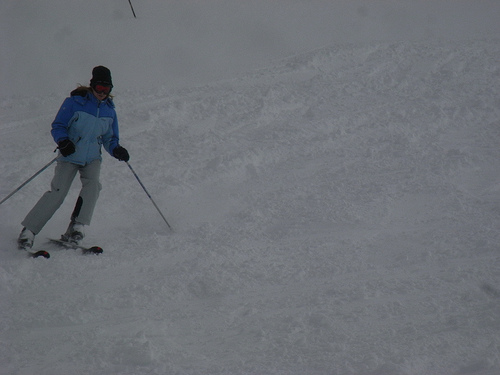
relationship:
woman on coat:
[18, 64, 130, 251] [50, 90, 118, 162]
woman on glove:
[18, 64, 130, 251] [109, 145, 130, 162]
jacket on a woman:
[40, 85, 124, 166] [18, 64, 130, 251]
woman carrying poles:
[18, 64, 130, 251] [126, 163, 176, 231]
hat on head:
[83, 60, 116, 94] [83, 51, 133, 102]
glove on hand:
[113, 143, 130, 160] [54, 134, 130, 165]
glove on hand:
[53, 137, 77, 157] [54, 134, 130, 165]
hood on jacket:
[70, 81, 95, 98] [50, 84, 123, 168]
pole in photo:
[1, 140, 71, 216] [2, 2, 483, 372]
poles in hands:
[0, 148, 176, 231] [59, 135, 134, 177]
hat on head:
[90, 65, 115, 86] [82, 51, 137, 103]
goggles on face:
[78, 76, 115, 102] [91, 76, 115, 95]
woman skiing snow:
[18, 64, 130, 251] [1, 0, 498, 374]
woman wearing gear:
[18, 64, 130, 251] [3, 141, 168, 247]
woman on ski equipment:
[18, 64, 130, 251] [23, 244, 51, 261]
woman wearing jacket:
[18, 64, 130, 251] [49, 87, 121, 163]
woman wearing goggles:
[18, 64, 130, 251] [92, 85, 113, 93]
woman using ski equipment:
[18, 64, 130, 251] [23, 244, 51, 261]